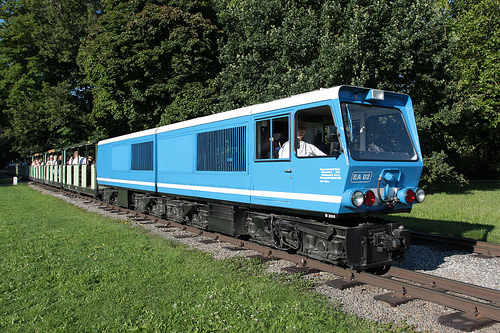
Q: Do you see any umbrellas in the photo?
A: No, there are no umbrellas.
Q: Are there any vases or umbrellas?
A: No, there are no umbrellas or vases.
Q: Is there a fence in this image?
A: No, there are no fences.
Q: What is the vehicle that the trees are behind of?
A: The vehicle is a train.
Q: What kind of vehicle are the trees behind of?
A: The trees are behind the train.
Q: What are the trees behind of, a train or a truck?
A: The trees are behind a train.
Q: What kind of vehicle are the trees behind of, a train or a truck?
A: The trees are behind a train.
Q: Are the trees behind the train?
A: Yes, the trees are behind the train.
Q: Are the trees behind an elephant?
A: No, the trees are behind the train.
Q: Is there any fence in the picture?
A: No, there are no fences.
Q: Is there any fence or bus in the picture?
A: No, there are no fences or buses.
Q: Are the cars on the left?
A: Yes, the cars are on the left of the image.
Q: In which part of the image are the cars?
A: The cars are on the left of the image.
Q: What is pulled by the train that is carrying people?
A: The cars are pulled by the train.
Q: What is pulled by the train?
A: The cars are pulled by the train.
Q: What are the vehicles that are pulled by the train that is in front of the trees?
A: The vehicles are cars.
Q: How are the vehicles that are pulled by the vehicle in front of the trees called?
A: The vehicles are cars.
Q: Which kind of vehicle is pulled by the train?
A: The vehicles are cars.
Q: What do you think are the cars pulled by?
A: The cars are pulled by the train.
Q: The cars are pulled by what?
A: The cars are pulled by the train.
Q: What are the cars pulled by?
A: The cars are pulled by the train.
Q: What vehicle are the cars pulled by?
A: The cars are pulled by the train.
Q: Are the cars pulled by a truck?
A: No, the cars are pulled by the train.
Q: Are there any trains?
A: Yes, there is a train.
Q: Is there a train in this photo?
A: Yes, there is a train.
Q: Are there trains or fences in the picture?
A: Yes, there is a train.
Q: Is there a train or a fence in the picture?
A: Yes, there is a train.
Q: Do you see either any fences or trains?
A: Yes, there is a train.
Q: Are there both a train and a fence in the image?
A: No, there is a train but no fences.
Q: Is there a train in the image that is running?
A: Yes, there is a train that is running.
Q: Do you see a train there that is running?
A: Yes, there is a train that is running.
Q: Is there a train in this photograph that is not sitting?
A: Yes, there is a train that is running.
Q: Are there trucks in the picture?
A: No, there are no trucks.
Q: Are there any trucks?
A: No, there are no trucks.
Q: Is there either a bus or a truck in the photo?
A: No, there are no trucks or buses.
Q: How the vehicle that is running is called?
A: The vehicle is a train.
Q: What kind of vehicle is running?
A: The vehicle is a train.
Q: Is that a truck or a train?
A: That is a train.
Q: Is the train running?
A: Yes, the train is running.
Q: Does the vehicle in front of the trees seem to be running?
A: Yes, the train is running.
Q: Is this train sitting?
A: No, the train is running.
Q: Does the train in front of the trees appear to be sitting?
A: No, the train is running.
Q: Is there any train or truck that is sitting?
A: No, there is a train but it is running.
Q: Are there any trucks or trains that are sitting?
A: No, there is a train but it is running.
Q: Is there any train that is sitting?
A: No, there is a train but it is running.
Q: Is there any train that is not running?
A: No, there is a train but it is running.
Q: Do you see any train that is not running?
A: No, there is a train but it is running.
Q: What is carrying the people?
A: The train is carrying the people.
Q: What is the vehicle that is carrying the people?
A: The vehicle is a train.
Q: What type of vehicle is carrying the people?
A: The vehicle is a train.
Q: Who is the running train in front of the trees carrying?
A: The train is carrying people.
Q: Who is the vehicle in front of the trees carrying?
A: The train is carrying people.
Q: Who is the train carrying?
A: The train is carrying people.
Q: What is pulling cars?
A: The train is pulling cars.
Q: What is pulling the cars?
A: The train is pulling cars.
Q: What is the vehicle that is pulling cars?
A: The vehicle is a train.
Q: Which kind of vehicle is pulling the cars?
A: The vehicle is a train.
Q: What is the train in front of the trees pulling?
A: The train is pulling cars.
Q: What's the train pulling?
A: The train is pulling cars.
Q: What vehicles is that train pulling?
A: The train is pulling cars.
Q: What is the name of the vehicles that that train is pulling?
A: The vehicles are cars.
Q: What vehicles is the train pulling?
A: The train is pulling cars.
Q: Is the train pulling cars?
A: Yes, the train is pulling cars.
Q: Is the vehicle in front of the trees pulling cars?
A: Yes, the train is pulling cars.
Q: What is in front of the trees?
A: The train is in front of the trees.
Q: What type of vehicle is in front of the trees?
A: The vehicle is a train.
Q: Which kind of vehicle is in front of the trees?
A: The vehicle is a train.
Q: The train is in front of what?
A: The train is in front of the trees.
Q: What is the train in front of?
A: The train is in front of the trees.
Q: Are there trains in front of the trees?
A: Yes, there is a train in front of the trees.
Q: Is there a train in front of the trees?
A: Yes, there is a train in front of the trees.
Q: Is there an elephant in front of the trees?
A: No, there is a train in front of the trees.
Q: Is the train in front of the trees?
A: Yes, the train is in front of the trees.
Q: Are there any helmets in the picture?
A: No, there are no helmets.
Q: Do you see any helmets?
A: No, there are no helmets.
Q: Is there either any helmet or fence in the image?
A: No, there are no helmets or fences.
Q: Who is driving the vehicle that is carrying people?
A: The man is driving the train.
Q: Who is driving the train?
A: The man is driving the train.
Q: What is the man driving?
A: The man is driving the train.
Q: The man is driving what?
A: The man is driving the train.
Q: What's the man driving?
A: The man is driving the train.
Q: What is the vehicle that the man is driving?
A: The vehicle is a train.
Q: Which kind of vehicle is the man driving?
A: The man is driving the train.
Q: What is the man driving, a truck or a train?
A: The man is driving a train.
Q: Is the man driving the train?
A: Yes, the man is driving the train.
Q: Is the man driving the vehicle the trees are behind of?
A: Yes, the man is driving the train.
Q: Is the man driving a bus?
A: No, the man is driving the train.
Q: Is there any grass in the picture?
A: Yes, there is grass.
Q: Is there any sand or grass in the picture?
A: Yes, there is grass.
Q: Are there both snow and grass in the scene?
A: No, there is grass but no snow.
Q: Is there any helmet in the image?
A: No, there are no helmets.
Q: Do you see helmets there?
A: No, there are no helmets.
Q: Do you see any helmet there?
A: No, there are no helmets.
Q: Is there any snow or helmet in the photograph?
A: No, there are no helmets or snow.